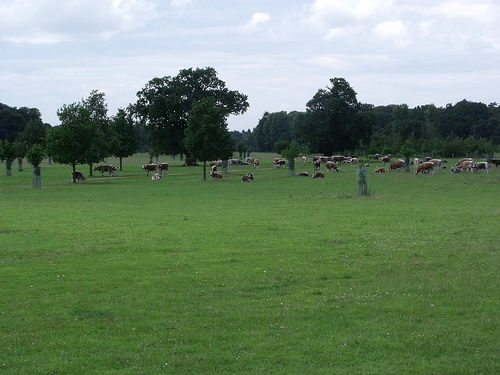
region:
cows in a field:
[396, 153, 479, 180]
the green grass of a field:
[195, 248, 267, 321]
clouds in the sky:
[320, 0, 408, 48]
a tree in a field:
[182, 101, 233, 185]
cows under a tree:
[286, 146, 340, 186]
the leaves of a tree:
[194, 122, 219, 154]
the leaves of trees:
[399, 111, 440, 138]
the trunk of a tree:
[199, 157, 210, 181]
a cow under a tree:
[58, 138, 93, 190]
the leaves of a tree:
[68, 122, 90, 147]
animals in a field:
[79, 110, 478, 257]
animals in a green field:
[53, 88, 493, 269]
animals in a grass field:
[46, 80, 496, 263]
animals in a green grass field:
[59, 93, 496, 260]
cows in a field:
[51, 73, 496, 290]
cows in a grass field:
[12, 74, 497, 306]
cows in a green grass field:
[34, 92, 499, 278]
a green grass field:
[62, 181, 454, 353]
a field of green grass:
[91, 189, 374, 371]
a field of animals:
[16, 95, 471, 271]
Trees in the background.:
[74, 50, 448, 208]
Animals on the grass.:
[74, 87, 471, 198]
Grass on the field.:
[34, 130, 400, 281]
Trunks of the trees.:
[53, 134, 486, 199]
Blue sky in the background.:
[103, 59, 315, 133]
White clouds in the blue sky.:
[72, 14, 372, 107]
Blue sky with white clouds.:
[118, 5, 388, 122]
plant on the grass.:
[321, 146, 416, 216]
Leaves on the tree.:
[54, 76, 221, 146]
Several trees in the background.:
[54, 67, 474, 221]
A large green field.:
[1, 0, 497, 373]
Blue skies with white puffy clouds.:
[1, 1, 498, 168]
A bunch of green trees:
[2, 58, 498, 210]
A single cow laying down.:
[235, 167, 259, 186]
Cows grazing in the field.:
[360, 138, 497, 227]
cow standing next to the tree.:
[42, 112, 107, 197]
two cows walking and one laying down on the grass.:
[132, 154, 180, 200]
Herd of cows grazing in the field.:
[0, 116, 498, 236]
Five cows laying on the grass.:
[145, 167, 332, 188]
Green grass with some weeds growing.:
[1, 192, 497, 374]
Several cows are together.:
[13, 131, 491, 203]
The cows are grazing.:
[43, 140, 491, 201]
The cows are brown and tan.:
[51, 142, 491, 194]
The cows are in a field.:
[0, 133, 499, 372]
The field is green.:
[0, 188, 497, 373]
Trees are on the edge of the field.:
[0, 62, 499, 174]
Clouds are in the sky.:
[0, 1, 498, 68]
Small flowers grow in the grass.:
[244, 268, 430, 321]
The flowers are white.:
[254, 260, 452, 342]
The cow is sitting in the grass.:
[230, 167, 267, 190]